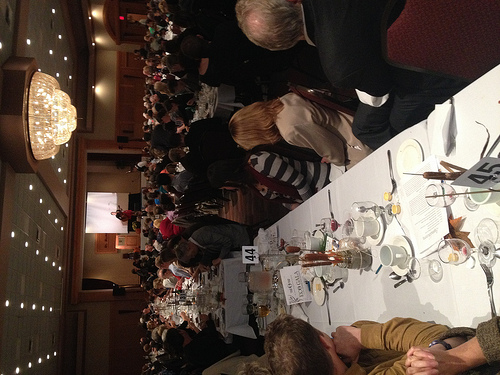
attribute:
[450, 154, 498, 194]
sign — white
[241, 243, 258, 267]
44 — black, white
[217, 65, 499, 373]
table — long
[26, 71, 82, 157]
chandelier — glass, white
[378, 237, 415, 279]
cup and saucer — white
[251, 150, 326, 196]
shirt — striped, grey, black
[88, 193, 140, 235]
screen — up front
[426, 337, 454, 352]
watch — black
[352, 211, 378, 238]
cup — white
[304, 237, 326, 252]
cup — white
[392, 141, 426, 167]
plate — white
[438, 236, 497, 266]
glass — clear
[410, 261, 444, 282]
glass — clear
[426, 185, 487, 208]
glass — clear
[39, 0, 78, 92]
tiny lights — lit